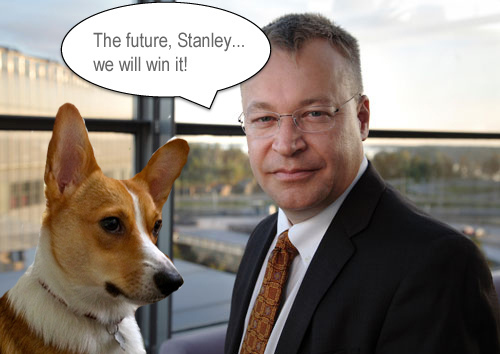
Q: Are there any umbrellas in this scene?
A: No, there are no umbrellas.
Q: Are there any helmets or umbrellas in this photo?
A: No, there are no umbrellas or helmets.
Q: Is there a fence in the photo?
A: No, there are no fences.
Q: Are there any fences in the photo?
A: No, there are no fences.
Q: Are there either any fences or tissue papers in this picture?
A: No, there are no fences or tissue papers.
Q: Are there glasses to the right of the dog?
A: Yes, there are glasses to the right of the dog.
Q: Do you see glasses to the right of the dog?
A: Yes, there are glasses to the right of the dog.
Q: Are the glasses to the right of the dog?
A: Yes, the glasses are to the right of the dog.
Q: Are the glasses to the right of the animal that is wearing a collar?
A: Yes, the glasses are to the right of the dog.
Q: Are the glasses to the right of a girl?
A: No, the glasses are to the right of the dog.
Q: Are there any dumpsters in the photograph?
A: No, there are no dumpsters.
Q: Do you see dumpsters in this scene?
A: No, there are no dumpsters.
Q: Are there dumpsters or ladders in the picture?
A: No, there are no dumpsters or ladders.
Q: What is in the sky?
A: The clouds are in the sky.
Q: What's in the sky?
A: The clouds are in the sky.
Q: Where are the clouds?
A: The clouds are in the sky.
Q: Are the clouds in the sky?
A: Yes, the clouds are in the sky.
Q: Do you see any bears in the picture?
A: No, there are no bears.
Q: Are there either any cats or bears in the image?
A: No, there are no bears or cats.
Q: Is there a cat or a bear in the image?
A: No, there are no bears or cats.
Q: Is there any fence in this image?
A: No, there are no fences.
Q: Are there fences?
A: No, there are no fences.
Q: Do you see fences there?
A: No, there are no fences.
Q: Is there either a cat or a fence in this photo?
A: No, there are no fences or cats.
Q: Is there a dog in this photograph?
A: Yes, there is a dog.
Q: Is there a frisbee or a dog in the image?
A: Yes, there is a dog.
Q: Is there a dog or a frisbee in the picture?
A: Yes, there is a dog.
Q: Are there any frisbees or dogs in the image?
A: Yes, there is a dog.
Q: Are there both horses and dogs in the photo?
A: No, there is a dog but no horses.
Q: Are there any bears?
A: No, there are no bears.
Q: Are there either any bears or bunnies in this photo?
A: No, there are no bears or bunnies.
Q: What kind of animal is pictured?
A: The animal is a dog.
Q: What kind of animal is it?
A: The animal is a dog.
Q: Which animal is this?
A: This is a dog.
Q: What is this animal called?
A: This is a dog.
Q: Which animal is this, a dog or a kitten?
A: This is a dog.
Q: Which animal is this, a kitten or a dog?
A: This is a dog.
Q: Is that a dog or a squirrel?
A: That is a dog.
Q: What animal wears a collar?
A: The dog wears a collar.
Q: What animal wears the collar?
A: The dog wears a collar.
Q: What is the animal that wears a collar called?
A: The animal is a dog.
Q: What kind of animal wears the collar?
A: The animal is a dog.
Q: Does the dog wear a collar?
A: Yes, the dog wears a collar.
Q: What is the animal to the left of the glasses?
A: The animal is a dog.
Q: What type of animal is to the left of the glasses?
A: The animal is a dog.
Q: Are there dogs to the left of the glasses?
A: Yes, there is a dog to the left of the glasses.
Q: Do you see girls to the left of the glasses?
A: No, there is a dog to the left of the glasses.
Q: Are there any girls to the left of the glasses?
A: No, there is a dog to the left of the glasses.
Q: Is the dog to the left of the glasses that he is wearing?
A: Yes, the dog is to the left of the glasses.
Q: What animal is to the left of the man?
A: The animal is a dog.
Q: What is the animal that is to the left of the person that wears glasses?
A: The animal is a dog.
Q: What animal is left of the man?
A: The animal is a dog.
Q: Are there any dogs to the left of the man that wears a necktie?
A: Yes, there is a dog to the left of the man.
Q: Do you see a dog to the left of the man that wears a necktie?
A: Yes, there is a dog to the left of the man.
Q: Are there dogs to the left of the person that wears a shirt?
A: Yes, there is a dog to the left of the man.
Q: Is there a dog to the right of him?
A: No, the dog is to the left of the man.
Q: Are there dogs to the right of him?
A: No, the dog is to the left of the man.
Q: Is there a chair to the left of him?
A: No, there is a dog to the left of the man.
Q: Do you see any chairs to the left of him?
A: No, there is a dog to the left of the man.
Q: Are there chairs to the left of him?
A: No, there is a dog to the left of the man.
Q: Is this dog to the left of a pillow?
A: No, the dog is to the left of the man.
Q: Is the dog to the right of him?
A: No, the dog is to the left of the man.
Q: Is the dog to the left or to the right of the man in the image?
A: The dog is to the left of the man.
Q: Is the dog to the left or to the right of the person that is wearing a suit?
A: The dog is to the left of the man.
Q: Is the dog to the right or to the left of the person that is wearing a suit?
A: The dog is to the left of the man.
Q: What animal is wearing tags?
A: The animal is a dog.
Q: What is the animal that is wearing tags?
A: The animal is a dog.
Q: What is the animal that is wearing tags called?
A: The animal is a dog.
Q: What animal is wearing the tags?
A: The animal is a dog.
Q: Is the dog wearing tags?
A: Yes, the dog is wearing tags.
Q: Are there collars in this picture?
A: Yes, there is a collar.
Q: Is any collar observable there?
A: Yes, there is a collar.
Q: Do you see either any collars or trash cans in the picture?
A: Yes, there is a collar.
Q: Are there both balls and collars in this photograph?
A: No, there is a collar but no balls.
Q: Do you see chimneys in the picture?
A: No, there are no chimneys.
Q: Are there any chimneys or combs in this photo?
A: No, there are no chimneys or combs.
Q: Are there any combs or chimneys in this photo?
A: No, there are no chimneys or combs.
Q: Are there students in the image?
A: No, there are no students.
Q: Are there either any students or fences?
A: No, there are no students or fences.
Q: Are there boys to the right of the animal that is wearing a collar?
A: No, there is a man to the right of the dog.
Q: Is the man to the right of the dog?
A: Yes, the man is to the right of the dog.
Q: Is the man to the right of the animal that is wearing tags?
A: Yes, the man is to the right of the dog.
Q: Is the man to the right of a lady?
A: No, the man is to the right of the dog.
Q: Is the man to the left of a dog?
A: No, the man is to the right of a dog.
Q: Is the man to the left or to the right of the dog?
A: The man is to the right of the dog.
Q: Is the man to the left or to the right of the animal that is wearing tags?
A: The man is to the right of the dog.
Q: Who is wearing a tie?
A: The man is wearing a tie.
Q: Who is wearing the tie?
A: The man is wearing a tie.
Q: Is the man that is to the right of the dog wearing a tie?
A: Yes, the man is wearing a tie.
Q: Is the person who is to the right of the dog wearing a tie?
A: Yes, the man is wearing a tie.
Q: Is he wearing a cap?
A: No, the man is wearing a tie.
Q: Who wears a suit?
A: The man wears a suit.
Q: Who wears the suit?
A: The man wears a suit.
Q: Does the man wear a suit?
A: Yes, the man wears a suit.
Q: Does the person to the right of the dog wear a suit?
A: Yes, the man wears a suit.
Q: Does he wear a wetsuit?
A: No, the man wears a suit.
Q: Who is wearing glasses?
A: The man is wearing glasses.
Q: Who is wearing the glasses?
A: The man is wearing glasses.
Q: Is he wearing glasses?
A: Yes, the man is wearing glasses.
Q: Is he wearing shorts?
A: No, the man is wearing glasses.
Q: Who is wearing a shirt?
A: The man is wearing a shirt.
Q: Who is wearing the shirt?
A: The man is wearing a shirt.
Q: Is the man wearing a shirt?
A: Yes, the man is wearing a shirt.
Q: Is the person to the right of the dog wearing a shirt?
A: Yes, the man is wearing a shirt.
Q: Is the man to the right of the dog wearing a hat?
A: No, the man is wearing a shirt.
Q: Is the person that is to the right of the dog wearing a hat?
A: No, the man is wearing a shirt.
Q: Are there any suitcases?
A: No, there are no suitcases.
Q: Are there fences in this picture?
A: No, there are no fences.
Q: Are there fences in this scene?
A: No, there are no fences.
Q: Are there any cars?
A: No, there are no cars.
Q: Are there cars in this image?
A: No, there are no cars.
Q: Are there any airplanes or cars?
A: No, there are no cars or airplanes.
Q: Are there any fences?
A: No, there are no fences.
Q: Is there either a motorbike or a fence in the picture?
A: No, there are no fences or motorcycles.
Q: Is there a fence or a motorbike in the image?
A: No, there are no fences or motorcycles.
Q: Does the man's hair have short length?
A: Yes, the hair is short.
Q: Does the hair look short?
A: Yes, the hair is short.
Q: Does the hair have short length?
A: Yes, the hair is short.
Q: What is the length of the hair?
A: The hair is short.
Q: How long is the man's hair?
A: The hair is short.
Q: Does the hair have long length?
A: No, the hair is short.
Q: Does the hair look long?
A: No, the hair is short.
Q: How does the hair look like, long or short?
A: The hair is short.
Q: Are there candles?
A: No, there are no candles.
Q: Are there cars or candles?
A: No, there are no candles or cars.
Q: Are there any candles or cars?
A: No, there are no candles or cars.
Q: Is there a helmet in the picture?
A: No, there are no helmets.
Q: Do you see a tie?
A: Yes, there is a tie.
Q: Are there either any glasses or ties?
A: Yes, there is a tie.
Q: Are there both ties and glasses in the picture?
A: Yes, there are both a tie and glasses.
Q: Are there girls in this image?
A: No, there are no girls.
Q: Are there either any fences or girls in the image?
A: No, there are no girls or fences.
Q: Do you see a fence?
A: No, there are no fences.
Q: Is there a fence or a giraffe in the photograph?
A: No, there are no fences or giraffes.